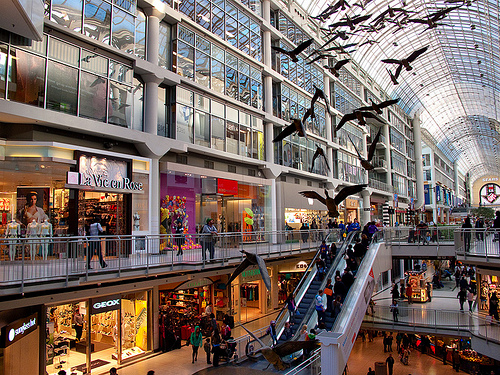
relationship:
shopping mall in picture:
[2, 2, 497, 373] [2, 4, 498, 364]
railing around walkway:
[367, 295, 497, 345] [232, 234, 392, 371]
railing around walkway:
[0, 231, 497, 290] [232, 234, 392, 371]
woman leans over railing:
[194, 217, 225, 272] [24, 227, 377, 293]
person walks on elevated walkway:
[82, 215, 110, 277] [9, 244, 327, 279]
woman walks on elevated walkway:
[196, 217, 218, 267] [9, 244, 327, 279]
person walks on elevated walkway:
[298, 223, 311, 243] [9, 244, 327, 279]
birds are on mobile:
[296, 184, 373, 223] [262, 3, 485, 249]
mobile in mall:
[262, 3, 485, 249] [176, 50, 491, 297]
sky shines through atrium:
[180, 20, 328, 110] [72, 20, 497, 151]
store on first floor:
[43, 287, 152, 373] [83, 312, 291, 372]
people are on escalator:
[263, 219, 381, 366] [252, 187, 423, 373]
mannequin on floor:
[4, 214, 21, 264] [5, 232, 354, 282]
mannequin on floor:
[22, 215, 38, 265] [5, 232, 354, 282]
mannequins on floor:
[35, 215, 51, 261] [5, 232, 354, 282]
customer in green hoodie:
[185, 323, 205, 365] [191, 325, 203, 350]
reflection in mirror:
[102, 39, 386, 155] [84, 290, 161, 370]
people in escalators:
[309, 219, 389, 341] [276, 212, 385, 358]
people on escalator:
[316, 239, 355, 321] [279, 230, 369, 373]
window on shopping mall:
[116, 285, 156, 368] [2, 2, 497, 373]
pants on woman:
[190, 345, 200, 361] [192, 325, 202, 360]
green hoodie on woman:
[188, 325, 203, 350] [192, 325, 202, 360]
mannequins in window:
[19, 193, 52, 259] [1, 144, 151, 283]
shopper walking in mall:
[453, 268, 476, 319] [1, 1, 498, 373]